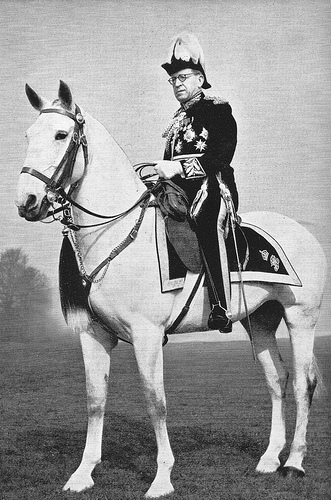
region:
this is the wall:
[65, 18, 117, 60]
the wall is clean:
[248, 124, 295, 177]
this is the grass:
[183, 405, 218, 472]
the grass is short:
[178, 401, 234, 470]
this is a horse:
[23, 81, 319, 493]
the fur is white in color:
[119, 301, 148, 316]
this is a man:
[143, 27, 251, 337]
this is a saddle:
[158, 193, 188, 242]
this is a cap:
[152, 27, 216, 79]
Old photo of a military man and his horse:
[10, 30, 329, 499]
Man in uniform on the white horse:
[150, 30, 250, 337]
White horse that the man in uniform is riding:
[12, 76, 328, 498]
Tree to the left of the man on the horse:
[1, 237, 57, 351]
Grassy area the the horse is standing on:
[0, 335, 330, 498]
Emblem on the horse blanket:
[254, 244, 284, 275]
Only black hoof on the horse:
[276, 463, 307, 481]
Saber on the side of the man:
[215, 170, 262, 368]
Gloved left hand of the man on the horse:
[149, 159, 188, 180]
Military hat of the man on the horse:
[158, 31, 211, 91]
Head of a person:
[153, 30, 224, 121]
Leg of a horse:
[281, 282, 330, 494]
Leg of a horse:
[241, 309, 290, 491]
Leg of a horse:
[125, 316, 195, 498]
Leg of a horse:
[57, 310, 126, 498]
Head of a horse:
[8, 73, 88, 235]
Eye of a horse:
[47, 120, 73, 148]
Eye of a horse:
[16, 121, 36, 146]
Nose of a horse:
[21, 189, 37, 210]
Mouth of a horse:
[14, 208, 52, 223]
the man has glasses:
[153, 63, 251, 332]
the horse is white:
[44, 105, 308, 488]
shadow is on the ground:
[63, 406, 210, 476]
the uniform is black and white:
[169, 112, 244, 302]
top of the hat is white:
[160, 27, 213, 73]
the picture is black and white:
[18, 47, 328, 498]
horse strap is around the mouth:
[20, 141, 94, 213]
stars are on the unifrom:
[176, 116, 218, 157]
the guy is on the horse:
[143, 53, 270, 316]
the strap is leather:
[53, 141, 80, 185]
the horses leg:
[130, 371, 202, 497]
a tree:
[1, 247, 48, 318]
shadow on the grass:
[176, 425, 214, 457]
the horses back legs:
[258, 378, 327, 493]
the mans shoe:
[209, 307, 233, 331]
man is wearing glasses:
[163, 75, 190, 84]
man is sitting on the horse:
[149, 38, 258, 320]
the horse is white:
[121, 275, 164, 314]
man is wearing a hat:
[162, 36, 205, 70]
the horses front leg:
[67, 388, 128, 483]